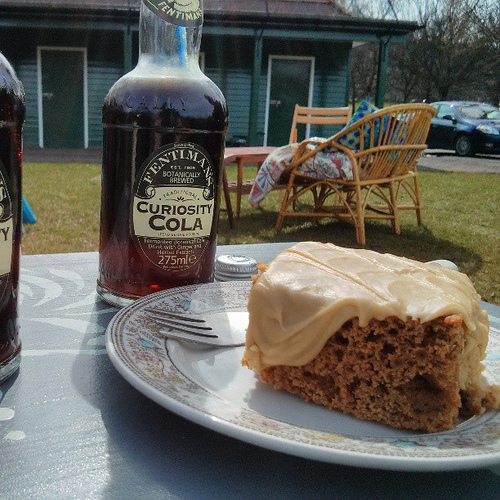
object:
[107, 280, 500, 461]
design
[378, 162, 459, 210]
ground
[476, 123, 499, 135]
headlight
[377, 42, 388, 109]
support pole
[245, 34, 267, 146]
support pole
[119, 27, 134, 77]
support pole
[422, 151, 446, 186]
ground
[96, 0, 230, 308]
glass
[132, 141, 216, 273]
jackson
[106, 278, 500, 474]
plate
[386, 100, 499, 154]
car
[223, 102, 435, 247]
furniture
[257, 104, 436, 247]
wicker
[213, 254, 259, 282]
bottlecap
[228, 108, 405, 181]
white blanket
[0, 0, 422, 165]
building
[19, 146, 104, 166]
porch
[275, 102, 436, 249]
bench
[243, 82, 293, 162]
wall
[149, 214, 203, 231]
cola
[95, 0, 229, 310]
bottle front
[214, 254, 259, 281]
cap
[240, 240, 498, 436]
carrot cake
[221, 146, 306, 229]
picnic table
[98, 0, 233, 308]
soda bottle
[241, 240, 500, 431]
cake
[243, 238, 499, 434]
icing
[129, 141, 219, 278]
label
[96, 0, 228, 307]
bottle